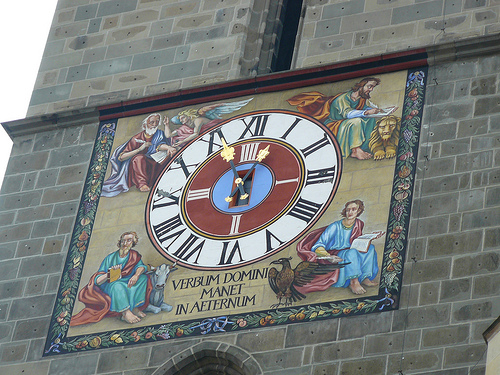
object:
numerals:
[299, 161, 339, 187]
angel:
[162, 96, 254, 148]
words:
[224, 271, 233, 284]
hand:
[217, 131, 250, 201]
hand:
[225, 144, 271, 203]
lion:
[367, 112, 404, 163]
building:
[0, 0, 499, 375]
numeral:
[214, 234, 245, 270]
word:
[171, 276, 182, 291]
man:
[91, 230, 157, 326]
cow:
[136, 258, 180, 316]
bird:
[263, 255, 353, 311]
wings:
[294, 259, 351, 288]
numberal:
[234, 107, 276, 142]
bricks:
[125, 43, 178, 72]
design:
[85, 132, 113, 188]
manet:
[196, 282, 248, 299]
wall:
[0, 0, 500, 375]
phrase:
[172, 267, 270, 315]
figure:
[40, 64, 429, 356]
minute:
[217, 136, 250, 201]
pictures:
[287, 76, 402, 163]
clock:
[144, 108, 350, 270]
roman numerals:
[259, 225, 286, 255]